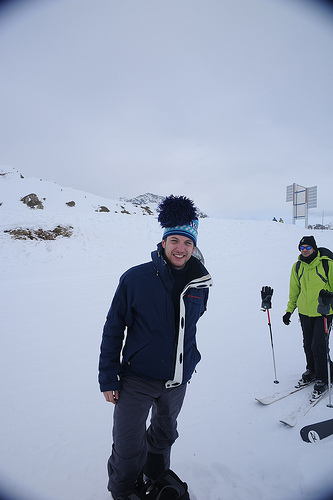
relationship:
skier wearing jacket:
[281, 234, 332, 399] [284, 246, 332, 319]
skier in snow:
[96, 214, 214, 497] [1, 169, 332, 498]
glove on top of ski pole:
[260, 286, 276, 310] [266, 309, 279, 384]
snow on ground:
[1, 169, 332, 498] [2, 169, 331, 498]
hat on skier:
[160, 213, 198, 247] [96, 214, 214, 497]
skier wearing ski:
[281, 234, 332, 399] [252, 381, 307, 405]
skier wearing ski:
[281, 234, 332, 399] [278, 382, 332, 428]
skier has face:
[281, 234, 332, 399] [297, 243, 315, 256]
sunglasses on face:
[298, 243, 313, 252] [297, 243, 315, 256]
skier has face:
[96, 214, 214, 497] [166, 234, 194, 267]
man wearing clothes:
[97, 194, 213, 498] [96, 241, 214, 488]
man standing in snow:
[97, 194, 213, 498] [1, 169, 332, 498]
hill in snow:
[1, 168, 332, 499] [1, 169, 332, 498]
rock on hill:
[22, 193, 41, 209] [1, 168, 332, 499]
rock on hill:
[62, 198, 76, 208] [1, 168, 332, 499]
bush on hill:
[5, 222, 75, 243] [1, 168, 332, 499]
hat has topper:
[160, 213, 198, 247] [157, 193, 198, 226]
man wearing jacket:
[282, 234, 332, 392] [284, 246, 332, 319]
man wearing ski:
[282, 234, 332, 392] [281, 384, 330, 428]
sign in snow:
[284, 181, 317, 228] [1, 169, 332, 498]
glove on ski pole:
[260, 284, 276, 310] [265, 307, 280, 386]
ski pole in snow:
[265, 307, 280, 386] [1, 169, 332, 498]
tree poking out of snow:
[278, 216, 285, 223] [1, 169, 332, 498]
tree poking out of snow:
[272, 215, 277, 222] [1, 169, 332, 498]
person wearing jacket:
[95, 210, 214, 498] [97, 241, 210, 389]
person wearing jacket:
[283, 235, 332, 396] [284, 246, 332, 319]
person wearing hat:
[95, 210, 214, 498] [163, 212, 198, 244]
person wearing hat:
[283, 235, 332, 396] [298, 235, 318, 252]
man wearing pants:
[97, 194, 213, 498] [107, 373, 186, 498]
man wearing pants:
[282, 234, 332, 392] [298, 312, 331, 382]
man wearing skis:
[282, 234, 332, 392] [254, 383, 327, 427]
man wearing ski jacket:
[97, 194, 213, 498] [98, 240, 211, 390]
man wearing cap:
[97, 194, 213, 498] [157, 194, 199, 243]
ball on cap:
[157, 195, 196, 228] [157, 194, 199, 243]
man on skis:
[282, 234, 332, 392] [254, 383, 327, 427]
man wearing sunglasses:
[282, 234, 332, 392] [298, 242, 313, 250]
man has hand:
[97, 194, 213, 498] [101, 390, 119, 403]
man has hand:
[282, 234, 332, 392] [281, 310, 293, 326]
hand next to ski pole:
[281, 310, 293, 326] [266, 309, 279, 384]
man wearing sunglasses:
[282, 234, 332, 392] [299, 244, 312, 250]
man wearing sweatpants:
[97, 194, 213, 498] [107, 375, 186, 499]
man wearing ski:
[282, 234, 332, 392] [255, 381, 313, 407]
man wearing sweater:
[282, 234, 332, 392] [285, 246, 332, 316]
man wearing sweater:
[97, 194, 213, 498] [97, 243, 213, 391]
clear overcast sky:
[66, 149, 134, 177] [24, 132, 326, 157]